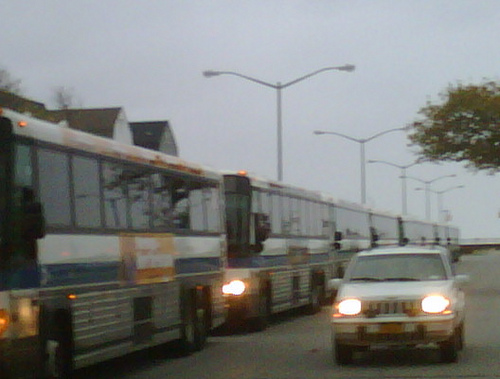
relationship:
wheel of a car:
[332, 340, 349, 363] [322, 242, 472, 362]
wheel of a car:
[440, 334, 456, 361] [322, 242, 472, 362]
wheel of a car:
[461, 322, 463, 346] [322, 242, 472, 362]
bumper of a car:
[334, 315, 455, 342] [322, 242, 472, 362]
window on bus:
[9, 141, 34, 190] [3, 108, 233, 377]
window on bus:
[33, 144, 73, 231] [3, 108, 233, 377]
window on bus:
[71, 150, 103, 230] [3, 108, 233, 377]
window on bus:
[102, 155, 132, 231] [3, 108, 233, 377]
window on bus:
[126, 160, 152, 230] [3, 108, 233, 377]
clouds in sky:
[0, 0, 499, 241] [2, 1, 493, 238]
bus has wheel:
[3, 108, 233, 377] [192, 287, 219, 340]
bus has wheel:
[3, 108, 233, 377] [177, 289, 202, 356]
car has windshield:
[325, 243, 469, 366] [347, 253, 451, 283]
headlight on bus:
[210, 267, 253, 301] [11, 162, 468, 354]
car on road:
[327, 243, 470, 369] [122, 250, 499, 377]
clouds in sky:
[164, 29, 342, 126] [55, 22, 493, 200]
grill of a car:
[362, 294, 422, 324] [306, 170, 455, 370]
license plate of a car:
[375, 319, 407, 337] [327, 243, 470, 369]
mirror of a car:
[319, 270, 345, 299] [322, 242, 472, 362]